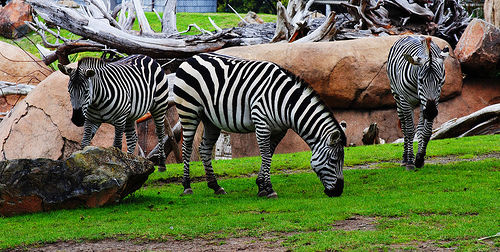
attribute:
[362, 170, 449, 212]
grass — not growing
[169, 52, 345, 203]
zebra — grazing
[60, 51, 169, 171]
zebra — white, black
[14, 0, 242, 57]
wood — for decoration, dead wood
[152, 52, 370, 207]
zebra — black, white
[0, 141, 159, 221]
rock — big, gray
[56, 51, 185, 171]
zebra — white, black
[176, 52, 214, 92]
stripe — black, white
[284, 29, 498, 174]
rock — in the background, large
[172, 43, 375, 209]
animal — white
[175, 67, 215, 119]
stripe — white, black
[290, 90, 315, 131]
stripe — white, black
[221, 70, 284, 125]
stripe — black, white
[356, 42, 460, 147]
zebra — walking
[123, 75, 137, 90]
fur — striped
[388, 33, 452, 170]
fur — striped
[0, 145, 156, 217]
rock — gray, big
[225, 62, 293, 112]
white stripe — black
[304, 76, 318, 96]
mane — black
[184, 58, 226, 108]
stripe — black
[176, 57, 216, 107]
stripe — white, black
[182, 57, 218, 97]
stripe — black, white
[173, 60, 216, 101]
stripe — black, white